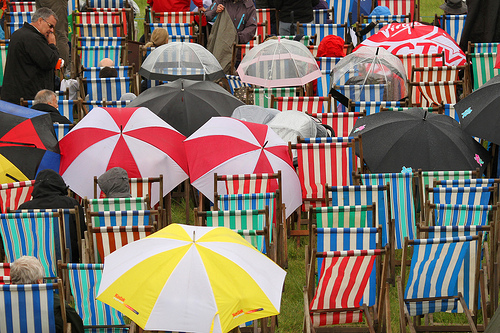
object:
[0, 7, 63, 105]
man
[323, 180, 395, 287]
seat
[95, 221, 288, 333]
umbrella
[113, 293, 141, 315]
writing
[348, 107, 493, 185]
umbrella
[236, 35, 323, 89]
umbrella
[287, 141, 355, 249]
chair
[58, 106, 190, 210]
umbrella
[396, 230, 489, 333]
chair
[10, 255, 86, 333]
man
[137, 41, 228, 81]
umbrella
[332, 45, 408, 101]
umbrella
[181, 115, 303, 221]
umbrella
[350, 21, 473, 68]
umbrella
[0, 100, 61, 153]
umbrella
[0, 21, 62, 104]
jacket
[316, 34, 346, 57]
hood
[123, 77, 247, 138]
umbrella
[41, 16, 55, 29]
sunglasses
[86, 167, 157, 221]
person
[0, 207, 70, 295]
chair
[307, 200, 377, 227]
chair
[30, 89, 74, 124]
person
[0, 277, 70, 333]
chair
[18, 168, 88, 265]
jacket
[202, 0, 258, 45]
jacket